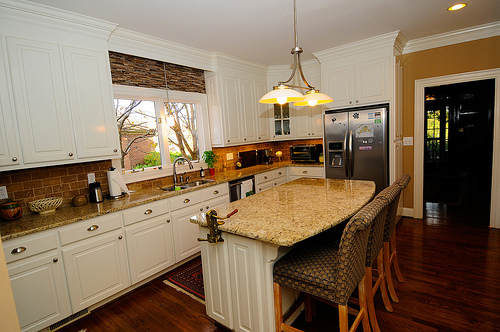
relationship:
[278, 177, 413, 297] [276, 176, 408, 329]
cushions on chairs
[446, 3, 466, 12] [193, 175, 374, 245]
light fixture over counter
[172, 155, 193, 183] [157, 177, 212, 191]
faucet in sink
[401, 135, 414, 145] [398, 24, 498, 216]
light switch on wall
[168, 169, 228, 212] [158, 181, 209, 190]
drawers under sink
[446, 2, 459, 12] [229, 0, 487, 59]
light fixture in ceiling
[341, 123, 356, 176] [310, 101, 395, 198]
handles on refrigerator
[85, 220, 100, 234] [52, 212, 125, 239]
handle of drawer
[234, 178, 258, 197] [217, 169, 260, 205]
towel hanging from dishwasher handle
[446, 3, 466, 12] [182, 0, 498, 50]
light fixture on ceiling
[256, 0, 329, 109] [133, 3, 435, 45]
lamp hanging from ceiling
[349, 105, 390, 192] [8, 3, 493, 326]
fridge in kitchen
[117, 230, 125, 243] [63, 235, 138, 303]
knob in cabinet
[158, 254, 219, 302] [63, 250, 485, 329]
rug on floor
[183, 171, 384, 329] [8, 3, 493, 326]
island in middle of kitchen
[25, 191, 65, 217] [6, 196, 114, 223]
basket on counter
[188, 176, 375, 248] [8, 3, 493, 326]
counter in middle of kitchen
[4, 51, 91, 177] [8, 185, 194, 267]
cabinets above counter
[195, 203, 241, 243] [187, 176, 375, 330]
grip on counter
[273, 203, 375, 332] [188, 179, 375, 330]
bar seat by island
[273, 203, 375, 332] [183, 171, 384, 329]
bar seat by island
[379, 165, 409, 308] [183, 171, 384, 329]
chair by island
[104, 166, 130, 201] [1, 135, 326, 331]
towels on counter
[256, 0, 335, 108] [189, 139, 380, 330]
lamp hanging above island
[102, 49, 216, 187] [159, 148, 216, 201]
window behind sink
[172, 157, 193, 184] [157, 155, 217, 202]
faucet in sink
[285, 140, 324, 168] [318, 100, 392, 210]
oven near refrigerator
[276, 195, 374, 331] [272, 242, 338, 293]
bar seat with cushion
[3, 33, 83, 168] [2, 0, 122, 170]
door for a cabinet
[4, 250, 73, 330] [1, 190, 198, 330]
door for a cabinet